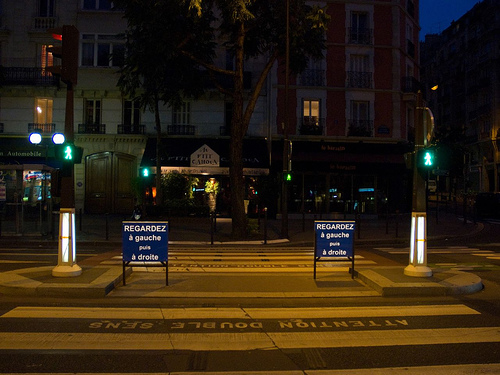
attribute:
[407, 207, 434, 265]
light — white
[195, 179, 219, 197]
light — white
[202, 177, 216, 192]
light — white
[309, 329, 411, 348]
stripe — white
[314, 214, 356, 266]
sign — blue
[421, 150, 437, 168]
light — green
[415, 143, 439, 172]
light — blue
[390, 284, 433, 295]
curb — white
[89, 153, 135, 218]
door — closed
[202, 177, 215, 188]
light — yellow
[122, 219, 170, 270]
sign — blue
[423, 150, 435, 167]
human figure — green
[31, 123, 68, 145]
street lamps — white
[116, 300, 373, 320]
stripe — white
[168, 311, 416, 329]
words — white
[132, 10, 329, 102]
tree — tall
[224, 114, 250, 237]
tree trunk — brown